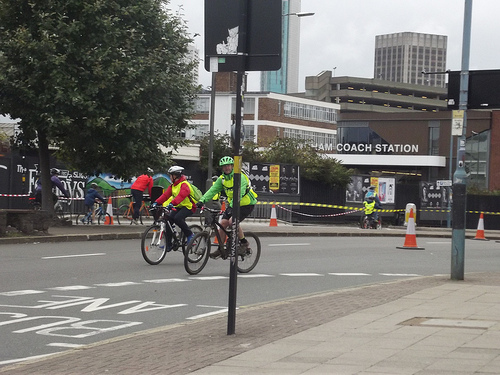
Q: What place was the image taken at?
A: It was taken at the street.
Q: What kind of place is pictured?
A: It is a street.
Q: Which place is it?
A: It is a street.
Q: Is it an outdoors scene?
A: Yes, it is outdoors.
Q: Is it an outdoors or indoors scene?
A: It is outdoors.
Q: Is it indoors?
A: No, it is outdoors.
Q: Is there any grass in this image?
A: Yes, there is grass.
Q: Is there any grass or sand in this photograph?
A: Yes, there is grass.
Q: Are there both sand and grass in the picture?
A: No, there is grass but no sand.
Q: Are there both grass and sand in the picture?
A: No, there is grass but no sand.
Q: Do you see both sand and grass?
A: No, there is grass but no sand.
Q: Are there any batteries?
A: No, there are no batteries.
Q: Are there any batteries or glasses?
A: No, there are no batteries or glasses.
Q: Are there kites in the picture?
A: No, there are no kites.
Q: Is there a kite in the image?
A: No, there are no kites.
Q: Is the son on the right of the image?
A: Yes, the son is on the right of the image.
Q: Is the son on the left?
A: No, the son is on the right of the image.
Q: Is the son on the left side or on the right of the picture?
A: The son is on the right of the image.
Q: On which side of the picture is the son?
A: The son is on the right of the image.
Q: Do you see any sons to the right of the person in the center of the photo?
A: Yes, there is a son to the right of the person.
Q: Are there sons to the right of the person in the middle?
A: Yes, there is a son to the right of the person.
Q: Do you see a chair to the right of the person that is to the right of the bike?
A: No, there is a son to the right of the person.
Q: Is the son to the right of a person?
A: Yes, the son is to the right of a person.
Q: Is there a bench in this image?
A: Yes, there is a bench.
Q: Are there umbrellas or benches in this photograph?
A: Yes, there is a bench.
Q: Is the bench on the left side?
A: Yes, the bench is on the left of the image.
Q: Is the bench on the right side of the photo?
A: No, the bench is on the left of the image.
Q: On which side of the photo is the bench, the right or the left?
A: The bench is on the left of the image.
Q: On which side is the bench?
A: The bench is on the left of the image.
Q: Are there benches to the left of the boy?
A: Yes, there is a bench to the left of the boy.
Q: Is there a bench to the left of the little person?
A: Yes, there is a bench to the left of the boy.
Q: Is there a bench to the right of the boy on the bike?
A: No, the bench is to the left of the boy.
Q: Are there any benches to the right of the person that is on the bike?
A: No, the bench is to the left of the boy.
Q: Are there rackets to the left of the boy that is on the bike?
A: No, there is a bench to the left of the boy.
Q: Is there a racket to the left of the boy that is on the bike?
A: No, there is a bench to the left of the boy.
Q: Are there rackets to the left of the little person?
A: No, there is a bench to the left of the boy.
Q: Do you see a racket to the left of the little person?
A: No, there is a bench to the left of the boy.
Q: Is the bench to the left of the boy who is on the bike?
A: Yes, the bench is to the left of the boy.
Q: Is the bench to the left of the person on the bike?
A: Yes, the bench is to the left of the boy.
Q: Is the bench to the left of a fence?
A: No, the bench is to the left of the boy.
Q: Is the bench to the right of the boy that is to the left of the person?
A: No, the bench is to the left of the boy.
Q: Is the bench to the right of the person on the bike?
A: No, the bench is to the left of the boy.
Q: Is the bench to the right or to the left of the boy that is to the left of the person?
A: The bench is to the left of the boy.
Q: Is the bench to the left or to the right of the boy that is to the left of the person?
A: The bench is to the left of the boy.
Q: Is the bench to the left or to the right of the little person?
A: The bench is to the left of the boy.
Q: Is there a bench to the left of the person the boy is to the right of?
A: Yes, there is a bench to the left of the person.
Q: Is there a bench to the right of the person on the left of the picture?
A: No, the bench is to the left of the person.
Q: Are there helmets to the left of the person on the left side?
A: No, there is a bench to the left of the person.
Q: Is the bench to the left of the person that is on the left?
A: Yes, the bench is to the left of the person.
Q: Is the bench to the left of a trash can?
A: No, the bench is to the left of the person.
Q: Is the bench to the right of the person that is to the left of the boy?
A: No, the bench is to the left of the person.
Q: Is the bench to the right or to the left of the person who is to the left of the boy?
A: The bench is to the left of the person.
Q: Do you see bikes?
A: Yes, there is a bike.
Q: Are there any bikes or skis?
A: Yes, there is a bike.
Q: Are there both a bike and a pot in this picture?
A: No, there is a bike but no pots.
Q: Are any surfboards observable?
A: No, there are no surfboards.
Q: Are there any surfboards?
A: No, there are no surfboards.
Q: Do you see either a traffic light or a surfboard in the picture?
A: No, there are no surfboards or traffic lights.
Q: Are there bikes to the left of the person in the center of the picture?
A: Yes, there is a bike to the left of the person.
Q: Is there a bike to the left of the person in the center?
A: Yes, there is a bike to the left of the person.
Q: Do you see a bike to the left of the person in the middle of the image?
A: Yes, there is a bike to the left of the person.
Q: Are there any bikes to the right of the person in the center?
A: No, the bike is to the left of the person.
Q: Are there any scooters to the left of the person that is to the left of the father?
A: No, there is a bike to the left of the person.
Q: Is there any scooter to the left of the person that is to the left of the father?
A: No, there is a bike to the left of the person.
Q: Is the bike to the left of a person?
A: Yes, the bike is to the left of a person.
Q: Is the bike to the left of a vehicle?
A: No, the bike is to the left of a person.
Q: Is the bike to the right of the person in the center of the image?
A: No, the bike is to the left of the person.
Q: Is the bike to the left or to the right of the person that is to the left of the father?
A: The bike is to the left of the person.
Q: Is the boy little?
A: Yes, the boy is little.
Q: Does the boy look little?
A: Yes, the boy is little.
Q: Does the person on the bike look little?
A: Yes, the boy is little.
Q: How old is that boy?
A: The boy is little.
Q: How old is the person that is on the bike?
A: The boy is little.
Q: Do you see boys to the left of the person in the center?
A: Yes, there is a boy to the left of the person.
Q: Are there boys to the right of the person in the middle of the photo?
A: No, the boy is to the left of the person.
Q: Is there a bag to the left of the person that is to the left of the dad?
A: No, there is a boy to the left of the person.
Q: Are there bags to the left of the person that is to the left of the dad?
A: No, there is a boy to the left of the person.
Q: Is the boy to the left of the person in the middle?
A: Yes, the boy is to the left of the person.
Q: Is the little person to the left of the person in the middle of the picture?
A: Yes, the boy is to the left of the person.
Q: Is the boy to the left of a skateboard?
A: No, the boy is to the left of the person.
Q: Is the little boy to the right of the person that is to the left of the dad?
A: No, the boy is to the left of the person.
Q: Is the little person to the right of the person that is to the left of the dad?
A: No, the boy is to the left of the person.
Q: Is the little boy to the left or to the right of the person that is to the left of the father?
A: The boy is to the left of the person.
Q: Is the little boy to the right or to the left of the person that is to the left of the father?
A: The boy is to the left of the person.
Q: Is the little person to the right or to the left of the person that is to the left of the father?
A: The boy is to the left of the person.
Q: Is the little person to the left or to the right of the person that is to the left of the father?
A: The boy is to the left of the person.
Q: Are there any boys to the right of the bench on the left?
A: Yes, there is a boy to the right of the bench.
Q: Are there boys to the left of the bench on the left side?
A: No, the boy is to the right of the bench.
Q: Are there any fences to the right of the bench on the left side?
A: No, there is a boy to the right of the bench.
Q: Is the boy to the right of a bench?
A: Yes, the boy is to the right of a bench.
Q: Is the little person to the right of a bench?
A: Yes, the boy is to the right of a bench.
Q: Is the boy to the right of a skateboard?
A: No, the boy is to the right of a bench.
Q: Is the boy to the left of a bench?
A: No, the boy is to the right of a bench.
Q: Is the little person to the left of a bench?
A: No, the boy is to the right of a bench.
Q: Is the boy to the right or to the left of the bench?
A: The boy is to the right of the bench.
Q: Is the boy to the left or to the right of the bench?
A: The boy is to the right of the bench.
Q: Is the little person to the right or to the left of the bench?
A: The boy is to the right of the bench.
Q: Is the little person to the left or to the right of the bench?
A: The boy is to the right of the bench.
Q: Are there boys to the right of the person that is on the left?
A: Yes, there is a boy to the right of the person.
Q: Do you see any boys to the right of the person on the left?
A: Yes, there is a boy to the right of the person.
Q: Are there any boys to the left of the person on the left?
A: No, the boy is to the right of the person.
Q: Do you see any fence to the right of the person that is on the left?
A: No, there is a boy to the right of the person.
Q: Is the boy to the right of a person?
A: Yes, the boy is to the right of a person.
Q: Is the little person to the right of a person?
A: Yes, the boy is to the right of a person.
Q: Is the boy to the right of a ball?
A: No, the boy is to the right of a person.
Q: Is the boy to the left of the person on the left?
A: No, the boy is to the right of the person.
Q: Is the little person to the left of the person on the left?
A: No, the boy is to the right of the person.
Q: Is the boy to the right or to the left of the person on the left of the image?
A: The boy is to the right of the person.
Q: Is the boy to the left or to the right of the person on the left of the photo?
A: The boy is to the right of the person.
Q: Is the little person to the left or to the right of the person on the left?
A: The boy is to the right of the person.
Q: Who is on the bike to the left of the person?
A: The boy is on the bike.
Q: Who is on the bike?
A: The boy is on the bike.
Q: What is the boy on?
A: The boy is on the bike.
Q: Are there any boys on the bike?
A: Yes, there is a boy on the bike.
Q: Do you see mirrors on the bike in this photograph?
A: No, there is a boy on the bike.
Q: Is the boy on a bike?
A: Yes, the boy is on a bike.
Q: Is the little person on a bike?
A: Yes, the boy is on a bike.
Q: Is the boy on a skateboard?
A: No, the boy is on a bike.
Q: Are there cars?
A: No, there are no cars.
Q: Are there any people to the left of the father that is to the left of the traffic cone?
A: Yes, there is a person to the left of the dad.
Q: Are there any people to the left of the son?
A: Yes, there is a person to the left of the son.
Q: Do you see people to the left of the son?
A: Yes, there is a person to the left of the son.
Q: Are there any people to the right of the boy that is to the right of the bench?
A: Yes, there is a person to the right of the boy.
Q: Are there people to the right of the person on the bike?
A: Yes, there is a person to the right of the boy.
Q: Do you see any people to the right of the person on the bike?
A: Yes, there is a person to the right of the boy.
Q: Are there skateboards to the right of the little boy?
A: No, there is a person to the right of the boy.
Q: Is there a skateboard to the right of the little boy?
A: No, there is a person to the right of the boy.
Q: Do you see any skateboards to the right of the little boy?
A: No, there is a person to the right of the boy.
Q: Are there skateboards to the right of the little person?
A: No, there is a person to the right of the boy.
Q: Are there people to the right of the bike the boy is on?
A: Yes, there is a person to the right of the bike.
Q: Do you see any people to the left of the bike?
A: No, the person is to the right of the bike.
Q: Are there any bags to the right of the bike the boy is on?
A: No, there is a person to the right of the bike.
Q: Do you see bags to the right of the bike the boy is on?
A: No, there is a person to the right of the bike.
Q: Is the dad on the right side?
A: Yes, the dad is on the right of the image.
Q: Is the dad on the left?
A: No, the dad is on the right of the image.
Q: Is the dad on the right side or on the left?
A: The dad is on the right of the image.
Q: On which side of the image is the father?
A: The father is on the right of the image.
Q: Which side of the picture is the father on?
A: The father is on the right of the image.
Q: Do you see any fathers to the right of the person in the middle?
A: Yes, there is a father to the right of the person.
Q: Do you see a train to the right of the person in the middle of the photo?
A: No, there is a father to the right of the person.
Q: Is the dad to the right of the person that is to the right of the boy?
A: Yes, the dad is to the right of the person.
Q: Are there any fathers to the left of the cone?
A: Yes, there is a father to the left of the cone.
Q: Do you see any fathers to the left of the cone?
A: Yes, there is a father to the left of the cone.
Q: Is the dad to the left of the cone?
A: Yes, the dad is to the left of the cone.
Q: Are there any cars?
A: No, there are no cars.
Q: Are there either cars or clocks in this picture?
A: No, there are no cars or clocks.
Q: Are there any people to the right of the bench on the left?
A: Yes, there is a person to the right of the bench.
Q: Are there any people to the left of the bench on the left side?
A: No, the person is to the right of the bench.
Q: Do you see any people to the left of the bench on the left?
A: No, the person is to the right of the bench.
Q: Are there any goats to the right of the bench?
A: No, there is a person to the right of the bench.